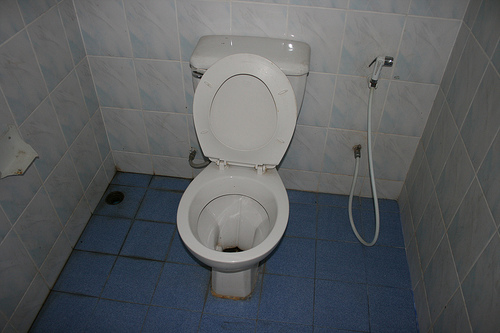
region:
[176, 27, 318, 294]
white toilet with raised lid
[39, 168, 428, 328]
blue tiled floor in toilet stall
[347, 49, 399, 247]
white spray nozzle attached to white cord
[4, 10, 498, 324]
light blue and white tile surrounding bathroom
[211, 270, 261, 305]
edge of toilet base yellowed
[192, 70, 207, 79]
silver flush handle on toilet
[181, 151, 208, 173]
metal coil connecting toilet to plumbing outlet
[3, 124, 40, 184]
white porcelain toilet roll holder on wall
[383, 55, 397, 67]
silver spout of spray gun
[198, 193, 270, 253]
empty interior of toilet bowl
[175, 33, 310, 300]
A white toilet.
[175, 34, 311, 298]
A toilet with no water in the bowl.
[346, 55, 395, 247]
A white hose with a spray nozzle attached.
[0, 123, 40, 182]
A broken toilet paper dispenser.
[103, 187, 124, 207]
A small drain is set into the floor.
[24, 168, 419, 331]
The floor is blue tiled.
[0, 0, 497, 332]
The walls are tiled in white.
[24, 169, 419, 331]
There is brownish grime between the tiles on the floor.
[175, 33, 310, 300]
The toilet seat is up.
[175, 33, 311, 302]
There is a thick build-up of grime at the base of the toilet.